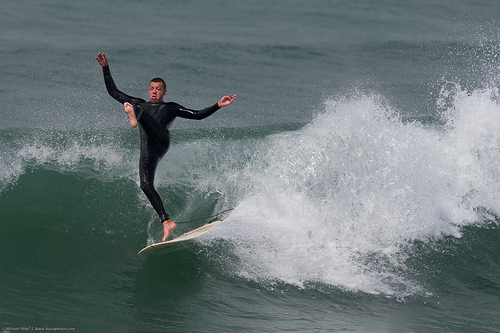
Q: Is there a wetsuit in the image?
A: Yes, there is a wetsuit.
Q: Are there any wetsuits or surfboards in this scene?
A: Yes, there is a wetsuit.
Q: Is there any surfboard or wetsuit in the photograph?
A: Yes, there is a wetsuit.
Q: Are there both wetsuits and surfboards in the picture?
A: Yes, there are both a wetsuit and a surfboard.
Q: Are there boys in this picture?
A: No, there are no boys.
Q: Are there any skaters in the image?
A: No, there are no skaters.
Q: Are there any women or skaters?
A: No, there are no skaters or women.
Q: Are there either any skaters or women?
A: No, there are no skaters or women.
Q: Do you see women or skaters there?
A: No, there are no skaters or women.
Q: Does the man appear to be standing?
A: Yes, the man is standing.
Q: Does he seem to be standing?
A: Yes, the man is standing.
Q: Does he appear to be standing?
A: Yes, the man is standing.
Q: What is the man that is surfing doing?
A: The man is standing.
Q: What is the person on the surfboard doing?
A: The man is standing.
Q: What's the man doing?
A: The man is standing.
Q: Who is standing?
A: The man is standing.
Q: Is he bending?
A: No, the man is standing.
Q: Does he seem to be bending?
A: No, the man is standing.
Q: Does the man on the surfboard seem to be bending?
A: No, the man is standing.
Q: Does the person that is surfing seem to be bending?
A: No, the man is standing.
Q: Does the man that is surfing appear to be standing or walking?
A: The man is standing.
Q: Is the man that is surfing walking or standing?
A: The man is standing.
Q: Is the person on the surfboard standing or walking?
A: The man is standing.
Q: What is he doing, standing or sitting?
A: The man is standing.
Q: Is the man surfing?
A: Yes, the man is surfing.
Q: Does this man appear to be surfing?
A: Yes, the man is surfing.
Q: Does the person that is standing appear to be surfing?
A: Yes, the man is surfing.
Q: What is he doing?
A: The man is surfing.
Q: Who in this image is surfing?
A: The man is surfing.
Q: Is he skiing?
A: No, the man is surfing.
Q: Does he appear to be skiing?
A: No, the man is surfing.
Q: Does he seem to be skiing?
A: No, the man is surfing.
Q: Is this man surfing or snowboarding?
A: The man is surfing.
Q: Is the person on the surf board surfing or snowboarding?
A: The man is surfing.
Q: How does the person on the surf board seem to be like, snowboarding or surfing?
A: The man is surfing.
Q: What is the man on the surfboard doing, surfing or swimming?
A: The man is surfing.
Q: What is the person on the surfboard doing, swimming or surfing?
A: The man is surfing.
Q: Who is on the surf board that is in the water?
A: The man is on the surfboard.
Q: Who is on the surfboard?
A: The man is on the surfboard.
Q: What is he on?
A: The man is on the surfboard.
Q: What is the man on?
A: The man is on the surfboard.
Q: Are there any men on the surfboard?
A: Yes, there is a man on the surfboard.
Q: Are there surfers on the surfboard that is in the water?
A: No, there is a man on the surfboard.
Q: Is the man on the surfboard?
A: Yes, the man is on the surfboard.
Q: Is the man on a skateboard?
A: No, the man is on the surfboard.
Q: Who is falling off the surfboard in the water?
A: The man is falling off the surfboard.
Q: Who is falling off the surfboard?
A: The man is falling off the surfboard.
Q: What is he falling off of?
A: The man is falling off the surfboard.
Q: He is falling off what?
A: The man is falling off the surfboard.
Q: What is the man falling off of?
A: The man is falling off the surfboard.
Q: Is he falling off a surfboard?
A: Yes, the man is falling off a surfboard.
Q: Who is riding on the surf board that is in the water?
A: The man is riding on the surfboard.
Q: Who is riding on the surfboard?
A: The man is riding on the surfboard.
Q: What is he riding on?
A: The man is riding on the surfboard.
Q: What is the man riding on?
A: The man is riding on the surfboard.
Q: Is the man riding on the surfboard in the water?
A: Yes, the man is riding on the surfboard.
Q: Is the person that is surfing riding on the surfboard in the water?
A: Yes, the man is riding on the surfboard.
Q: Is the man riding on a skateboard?
A: No, the man is riding on the surfboard.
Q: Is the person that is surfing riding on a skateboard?
A: No, the man is riding on the surfboard.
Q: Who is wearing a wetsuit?
A: The man is wearing a wetsuit.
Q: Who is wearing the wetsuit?
A: The man is wearing a wetsuit.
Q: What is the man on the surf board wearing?
A: The man is wearing a wetsuit.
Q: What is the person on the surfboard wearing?
A: The man is wearing a wetsuit.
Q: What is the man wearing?
A: The man is wearing a wetsuit.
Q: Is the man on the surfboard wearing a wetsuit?
A: Yes, the man is wearing a wetsuit.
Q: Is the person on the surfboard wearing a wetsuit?
A: Yes, the man is wearing a wetsuit.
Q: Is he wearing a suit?
A: No, the man is wearing a wetsuit.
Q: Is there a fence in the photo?
A: No, there are no fences.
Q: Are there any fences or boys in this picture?
A: No, there are no fences or boys.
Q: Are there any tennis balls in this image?
A: No, there are no tennis balls.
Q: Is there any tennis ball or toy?
A: No, there are no tennis balls or toys.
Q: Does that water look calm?
A: Yes, the water is calm.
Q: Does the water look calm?
A: Yes, the water is calm.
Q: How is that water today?
A: The water is calm.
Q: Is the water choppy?
A: No, the water is calm.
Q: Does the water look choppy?
A: No, the water is calm.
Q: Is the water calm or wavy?
A: The water is calm.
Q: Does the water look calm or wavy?
A: The water is calm.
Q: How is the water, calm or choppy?
A: The water is calm.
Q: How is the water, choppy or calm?
A: The water is calm.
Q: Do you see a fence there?
A: No, there are no fences.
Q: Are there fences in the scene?
A: No, there are no fences.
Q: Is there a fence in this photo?
A: No, there are no fences.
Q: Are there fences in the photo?
A: No, there are no fences.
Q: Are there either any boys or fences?
A: No, there are no fences or boys.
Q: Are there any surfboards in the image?
A: Yes, there is a surfboard.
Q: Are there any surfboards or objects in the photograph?
A: Yes, there is a surfboard.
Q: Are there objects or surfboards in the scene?
A: Yes, there is a surfboard.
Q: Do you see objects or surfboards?
A: Yes, there is a surfboard.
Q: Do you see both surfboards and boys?
A: No, there is a surfboard but no boys.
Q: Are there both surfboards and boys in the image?
A: No, there is a surfboard but no boys.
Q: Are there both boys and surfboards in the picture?
A: No, there is a surfboard but no boys.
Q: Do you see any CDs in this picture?
A: No, there are no cds.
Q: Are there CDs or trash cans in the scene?
A: No, there are no CDs or trash cans.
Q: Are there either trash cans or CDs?
A: No, there are no CDs or trash cans.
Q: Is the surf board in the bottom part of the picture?
A: Yes, the surf board is in the bottom of the image.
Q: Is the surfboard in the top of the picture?
A: No, the surfboard is in the bottom of the image.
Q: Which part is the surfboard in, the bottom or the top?
A: The surfboard is in the bottom of the image.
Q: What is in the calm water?
A: The surf board is in the water.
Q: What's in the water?
A: The surf board is in the water.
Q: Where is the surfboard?
A: The surfboard is in the water.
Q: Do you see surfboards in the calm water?
A: Yes, there is a surfboard in the water.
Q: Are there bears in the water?
A: No, there is a surfboard in the water.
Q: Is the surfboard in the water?
A: Yes, the surfboard is in the water.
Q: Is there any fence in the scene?
A: No, there are no fences.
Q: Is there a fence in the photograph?
A: No, there are no fences.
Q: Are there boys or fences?
A: No, there are no fences or boys.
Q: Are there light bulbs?
A: No, there are no light bulbs.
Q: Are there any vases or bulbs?
A: No, there are no bulbs or vases.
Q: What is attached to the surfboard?
A: The rope is attached to the surfboard.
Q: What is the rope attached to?
A: The rope is attached to the surfboard.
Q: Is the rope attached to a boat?
A: No, the rope is attached to the surf board.